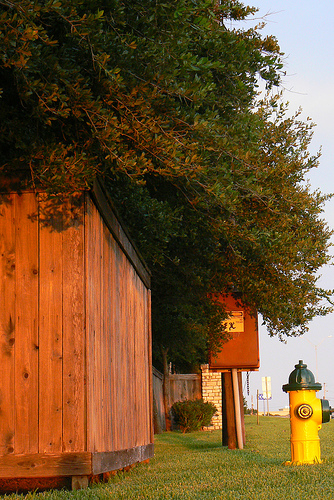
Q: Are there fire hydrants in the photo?
A: Yes, there is a fire hydrant.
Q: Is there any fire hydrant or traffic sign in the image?
A: Yes, there is a fire hydrant.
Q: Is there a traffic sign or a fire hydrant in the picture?
A: Yes, there is a fire hydrant.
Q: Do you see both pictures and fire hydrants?
A: No, there is a fire hydrant but no pictures.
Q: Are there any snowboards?
A: No, there are no snowboards.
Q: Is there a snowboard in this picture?
A: No, there are no snowboards.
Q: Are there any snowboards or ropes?
A: No, there are no snowboards or ropes.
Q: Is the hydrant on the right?
A: Yes, the hydrant is on the right of the image.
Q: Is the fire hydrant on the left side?
A: No, the fire hydrant is on the right of the image.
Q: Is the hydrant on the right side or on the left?
A: The hydrant is on the right of the image.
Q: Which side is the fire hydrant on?
A: The fire hydrant is on the right of the image.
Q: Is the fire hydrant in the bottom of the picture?
A: Yes, the fire hydrant is in the bottom of the image.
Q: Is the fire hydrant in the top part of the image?
A: No, the fire hydrant is in the bottom of the image.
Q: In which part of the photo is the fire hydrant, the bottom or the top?
A: The fire hydrant is in the bottom of the image.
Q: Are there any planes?
A: No, there are no planes.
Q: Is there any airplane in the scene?
A: No, there are no airplanes.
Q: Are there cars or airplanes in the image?
A: No, there are no airplanes or cars.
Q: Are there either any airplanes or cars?
A: No, there are no airplanes or cars.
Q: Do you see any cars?
A: No, there are no cars.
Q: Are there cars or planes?
A: No, there are no cars or planes.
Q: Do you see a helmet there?
A: No, there are no helmets.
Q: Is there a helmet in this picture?
A: No, there are no helmets.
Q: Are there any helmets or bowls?
A: No, there are no helmets or bowls.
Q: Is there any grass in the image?
A: Yes, there is grass.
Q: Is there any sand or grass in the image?
A: Yes, there is grass.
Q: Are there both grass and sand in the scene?
A: No, there is grass but no sand.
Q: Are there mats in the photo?
A: No, there are no mats.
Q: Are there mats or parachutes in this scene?
A: No, there are no mats or parachutes.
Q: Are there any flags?
A: No, there are no flags.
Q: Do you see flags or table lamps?
A: No, there are no flags or table lamps.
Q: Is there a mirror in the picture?
A: No, there are no mirrors.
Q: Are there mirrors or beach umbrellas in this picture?
A: No, there are no mirrors or beach umbrellas.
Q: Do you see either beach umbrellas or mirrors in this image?
A: No, there are no mirrors or beach umbrellas.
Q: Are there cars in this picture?
A: No, there are no cars.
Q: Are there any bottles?
A: No, there are no bottles.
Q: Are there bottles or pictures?
A: No, there are no bottles or pictures.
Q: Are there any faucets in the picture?
A: No, there are no faucets.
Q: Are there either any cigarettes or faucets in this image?
A: No, there are no faucets or cigarettes.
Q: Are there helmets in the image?
A: No, there are no helmets.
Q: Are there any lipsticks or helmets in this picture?
A: No, there are no helmets or lipsticks.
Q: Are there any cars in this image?
A: No, there are no cars.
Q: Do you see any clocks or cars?
A: No, there are no cars or clocks.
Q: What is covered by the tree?
A: The building is covered by the tree.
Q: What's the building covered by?
A: The building is covered by the tree.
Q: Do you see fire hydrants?
A: Yes, there is a fire hydrant.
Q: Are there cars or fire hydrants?
A: Yes, there is a fire hydrant.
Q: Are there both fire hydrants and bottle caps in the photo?
A: No, there is a fire hydrant but no bottle caps.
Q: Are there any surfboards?
A: No, there are no surfboards.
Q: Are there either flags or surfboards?
A: No, there are no surfboards or flags.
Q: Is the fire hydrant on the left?
A: No, the fire hydrant is on the right of the image.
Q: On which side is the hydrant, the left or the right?
A: The hydrant is on the right of the image.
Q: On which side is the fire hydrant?
A: The fire hydrant is on the right of the image.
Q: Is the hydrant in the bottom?
A: Yes, the hydrant is in the bottom of the image.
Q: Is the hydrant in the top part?
A: No, the hydrant is in the bottom of the image.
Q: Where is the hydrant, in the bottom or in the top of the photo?
A: The hydrant is in the bottom of the image.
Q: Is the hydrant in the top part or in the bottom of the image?
A: The hydrant is in the bottom of the image.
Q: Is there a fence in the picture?
A: Yes, there is a fence.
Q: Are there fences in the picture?
A: Yes, there is a fence.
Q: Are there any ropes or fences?
A: Yes, there is a fence.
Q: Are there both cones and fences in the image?
A: No, there is a fence but no cones.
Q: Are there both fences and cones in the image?
A: No, there is a fence but no cones.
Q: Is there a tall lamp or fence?
A: Yes, there is a tall fence.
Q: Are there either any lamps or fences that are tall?
A: Yes, the fence is tall.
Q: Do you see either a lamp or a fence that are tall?
A: Yes, the fence is tall.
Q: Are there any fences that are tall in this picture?
A: Yes, there is a tall fence.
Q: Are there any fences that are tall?
A: Yes, there is a fence that is tall.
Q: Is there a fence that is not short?
A: Yes, there is a tall fence.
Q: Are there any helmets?
A: No, there are no helmets.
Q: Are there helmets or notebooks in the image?
A: No, there are no helmets or notebooks.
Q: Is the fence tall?
A: Yes, the fence is tall.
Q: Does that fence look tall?
A: Yes, the fence is tall.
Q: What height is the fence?
A: The fence is tall.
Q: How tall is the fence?
A: The fence is tall.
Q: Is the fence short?
A: No, the fence is tall.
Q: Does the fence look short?
A: No, the fence is tall.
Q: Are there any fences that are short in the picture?
A: No, there is a fence but it is tall.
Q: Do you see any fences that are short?
A: No, there is a fence but it is tall.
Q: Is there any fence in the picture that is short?
A: No, there is a fence but it is tall.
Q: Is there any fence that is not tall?
A: No, there is a fence but it is tall.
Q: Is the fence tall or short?
A: The fence is tall.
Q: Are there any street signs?
A: Yes, there is a street sign.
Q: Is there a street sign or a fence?
A: Yes, there is a street sign.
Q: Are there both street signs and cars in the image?
A: No, there is a street sign but no cars.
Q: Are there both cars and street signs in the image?
A: No, there is a street sign but no cars.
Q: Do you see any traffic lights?
A: No, there are no traffic lights.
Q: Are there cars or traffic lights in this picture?
A: No, there are no traffic lights or cars.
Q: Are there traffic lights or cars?
A: No, there are no traffic lights or cars.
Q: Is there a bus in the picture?
A: No, there are no buses.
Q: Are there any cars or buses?
A: No, there are no buses or cars.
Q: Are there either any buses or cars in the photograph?
A: No, there are no buses or cars.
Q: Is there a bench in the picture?
A: No, there are no benches.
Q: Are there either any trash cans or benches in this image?
A: No, there are no benches or trash cans.